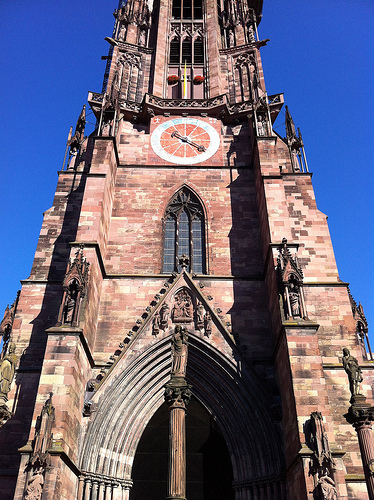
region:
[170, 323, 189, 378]
Statue of a woman above an arch.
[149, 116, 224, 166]
Square around a clock face.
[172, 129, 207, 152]
Two hands of a clock.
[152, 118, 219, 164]
A large round clock face on a building.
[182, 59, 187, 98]
A yellow point like a needle above the clock.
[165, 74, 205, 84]
Two bunches of red flowers above a clock.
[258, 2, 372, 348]
Dark blue sky to the right of the tower.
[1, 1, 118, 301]
Dark blue sky to the left of the tower.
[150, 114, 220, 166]
White round circle of a clock.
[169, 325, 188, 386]
A brown statue above the arched doorway.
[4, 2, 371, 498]
tall brick clock tower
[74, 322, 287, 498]
arched layered stone doorway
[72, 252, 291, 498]
arched tower entry door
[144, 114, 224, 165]
clock on tower face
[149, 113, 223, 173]
white circular clock over entry door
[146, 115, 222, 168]
white clock above arched doorway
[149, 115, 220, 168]
clock that reads four twenty two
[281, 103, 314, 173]
decorative spires to right of clock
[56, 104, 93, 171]
decorative spires to left of clock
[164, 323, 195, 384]
statue in front of entry door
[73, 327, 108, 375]
this is an old building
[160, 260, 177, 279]
this is a window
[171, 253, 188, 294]
the window is glass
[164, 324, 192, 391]
this is a statue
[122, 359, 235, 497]
there are no people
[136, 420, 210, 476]
this is a doorway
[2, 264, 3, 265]
there are no clouds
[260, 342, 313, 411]
this is made of bricks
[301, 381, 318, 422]
the building is red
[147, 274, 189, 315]
this is a panel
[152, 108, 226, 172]
clock in the building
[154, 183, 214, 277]
window of the building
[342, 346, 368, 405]
statue of the building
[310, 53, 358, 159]
a clear blue color sky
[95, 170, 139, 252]
building made with bricks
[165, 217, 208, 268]
window with glass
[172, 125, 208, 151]
needle in the clock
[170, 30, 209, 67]
window with the grill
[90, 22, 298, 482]
big building with lot of windows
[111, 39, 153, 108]
design of the building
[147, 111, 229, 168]
the clock only has one hand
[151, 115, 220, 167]
face of the clock is red and white with blue numbers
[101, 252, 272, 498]
decorative alcove of a church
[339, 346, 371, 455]
statue on a pillar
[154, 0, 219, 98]
an open bell tower of a church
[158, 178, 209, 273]
decorative window of a church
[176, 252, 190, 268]
small and thick decorative cross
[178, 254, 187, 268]
a small crucifix on the top of a doorway alcove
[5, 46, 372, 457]
the front entrance of a church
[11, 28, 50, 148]
bright blue cloudless sky